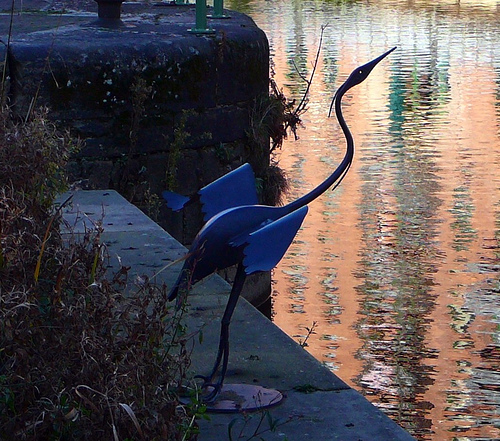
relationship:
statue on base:
[158, 42, 401, 413] [173, 378, 285, 414]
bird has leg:
[167, 46, 398, 404] [217, 271, 251, 393]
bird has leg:
[167, 46, 398, 404] [199, 267, 241, 393]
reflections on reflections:
[352, 75, 467, 297] [188, 0, 500, 441]